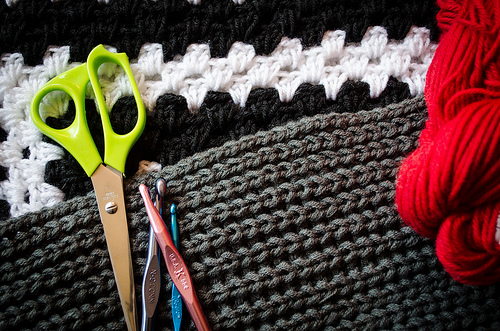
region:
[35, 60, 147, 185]
green handle of scissors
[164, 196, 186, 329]
blue metal pin on grey fabric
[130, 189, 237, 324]
pink metal pin on grey fabric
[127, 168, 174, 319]
grey pin on grey fabric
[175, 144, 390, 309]
grey knitted fabric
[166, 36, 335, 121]
black and white fabric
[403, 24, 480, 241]
red fabric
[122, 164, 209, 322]
three metal pins pile on each other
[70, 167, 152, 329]
grey metal blade of scissors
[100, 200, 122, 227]
grey screw of scissors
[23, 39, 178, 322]
the scissors' handles are yellow green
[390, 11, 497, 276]
the yarn is red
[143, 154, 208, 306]
the needles are red, gray and ble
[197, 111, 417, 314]
the crochet is gray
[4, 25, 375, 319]
the scissors is on top of the yarn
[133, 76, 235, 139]
the yarn is black and white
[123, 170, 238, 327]
three needles beside the scissors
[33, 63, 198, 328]
the scissors is silver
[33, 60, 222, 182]
a pair of scissors beside the needles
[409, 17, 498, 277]
a roll of yarn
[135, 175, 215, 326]
a group of three crochet hooks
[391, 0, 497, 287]
ball of bright red yarn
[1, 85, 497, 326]
a gray crocheted scarf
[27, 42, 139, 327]
a pair of bright green scissors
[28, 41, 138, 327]
scissors with green handle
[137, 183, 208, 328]
a pink crochet hook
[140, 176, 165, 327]
a gray crochet hook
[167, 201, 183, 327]
a blue crochet hook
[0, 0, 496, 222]
black and white scarf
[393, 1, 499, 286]
a ball of yarn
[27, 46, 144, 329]
Scissors are green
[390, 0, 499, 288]
Yarn is red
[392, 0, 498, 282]
Red yarn on top of gray knit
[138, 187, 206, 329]
Needle is red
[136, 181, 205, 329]
Red needle on top of blue needle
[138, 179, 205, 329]
Red needle on top of purple needle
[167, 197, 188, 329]
Blue needle below red needle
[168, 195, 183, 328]
Blue needle next to purple needle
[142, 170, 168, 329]
Purple needle below red needle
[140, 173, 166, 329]
Purple needle next to blue needle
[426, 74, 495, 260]
the yarn is red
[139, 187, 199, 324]
the tools are colorful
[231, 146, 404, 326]
one blanket is gray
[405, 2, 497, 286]
yarn is on blanket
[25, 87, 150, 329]
scissors are on blanket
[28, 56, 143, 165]
scissor handle is green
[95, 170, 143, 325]
scissor blades are silver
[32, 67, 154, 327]
one pair of scissors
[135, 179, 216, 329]
three tools for crochet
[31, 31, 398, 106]
one blanket is black and white